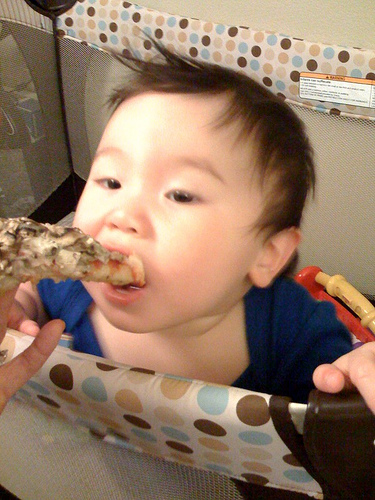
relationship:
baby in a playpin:
[3, 28, 373, 412] [2, 2, 374, 499]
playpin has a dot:
[2, 2, 374, 499] [307, 57, 317, 71]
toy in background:
[295, 266, 374, 346] [1, 2, 373, 291]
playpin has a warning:
[2, 2, 374, 499] [300, 71, 373, 107]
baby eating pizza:
[3, 28, 373, 412] [1, 220, 150, 289]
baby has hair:
[3, 28, 373, 412] [102, 27, 317, 229]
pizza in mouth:
[1, 220, 150, 289] [100, 248, 147, 302]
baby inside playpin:
[3, 28, 373, 412] [2, 2, 374, 499]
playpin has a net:
[2, 2, 374, 499] [59, 39, 374, 296]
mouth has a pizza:
[100, 248, 147, 302] [1, 220, 150, 289]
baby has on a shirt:
[3, 28, 373, 412] [41, 275, 352, 405]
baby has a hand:
[3, 28, 373, 412] [311, 342, 373, 418]